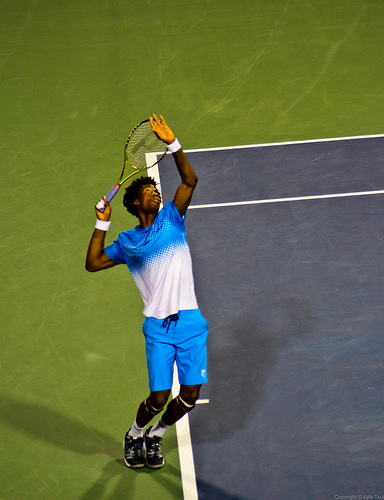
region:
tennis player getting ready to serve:
[75, 103, 220, 477]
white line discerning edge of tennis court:
[169, 385, 208, 498]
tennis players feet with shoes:
[113, 419, 181, 478]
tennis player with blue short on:
[134, 306, 216, 394]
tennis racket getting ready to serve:
[91, 113, 180, 224]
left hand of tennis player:
[144, 104, 182, 145]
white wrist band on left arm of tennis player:
[161, 134, 185, 158]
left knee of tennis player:
[178, 382, 203, 412]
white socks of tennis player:
[125, 417, 175, 441]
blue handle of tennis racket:
[92, 175, 127, 214]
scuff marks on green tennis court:
[36, 290, 57, 335]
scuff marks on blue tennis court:
[289, 220, 322, 241]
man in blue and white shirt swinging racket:
[84, 116, 197, 313]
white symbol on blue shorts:
[199, 368, 206, 379]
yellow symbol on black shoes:
[131, 435, 137, 438]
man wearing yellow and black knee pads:
[141, 398, 164, 419]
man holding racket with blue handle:
[92, 183, 118, 219]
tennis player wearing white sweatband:
[147, 111, 200, 157]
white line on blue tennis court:
[283, 192, 336, 203]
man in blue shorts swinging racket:
[81, 117, 203, 392]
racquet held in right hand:
[101, 118, 155, 212]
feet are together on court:
[120, 431, 179, 477]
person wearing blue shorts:
[137, 321, 218, 379]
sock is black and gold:
[157, 396, 195, 428]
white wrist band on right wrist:
[90, 219, 116, 226]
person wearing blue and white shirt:
[122, 216, 176, 313]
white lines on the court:
[198, 146, 382, 215]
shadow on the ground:
[5, 390, 133, 489]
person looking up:
[122, 175, 186, 244]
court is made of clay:
[221, 313, 378, 495]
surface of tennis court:
[3, 2, 383, 495]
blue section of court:
[143, 135, 380, 497]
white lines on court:
[145, 131, 381, 498]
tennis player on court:
[85, 115, 212, 469]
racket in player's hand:
[95, 118, 170, 216]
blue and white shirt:
[105, 200, 198, 318]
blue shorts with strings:
[143, 309, 209, 392]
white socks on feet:
[129, 419, 172, 437]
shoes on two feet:
[123, 425, 163, 467]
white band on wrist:
[166, 138, 181, 151]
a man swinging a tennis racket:
[92, 101, 230, 467]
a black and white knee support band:
[140, 396, 164, 416]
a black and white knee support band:
[173, 395, 196, 414]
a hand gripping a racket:
[94, 191, 111, 219]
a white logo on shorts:
[199, 366, 212, 379]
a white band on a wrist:
[92, 215, 115, 233]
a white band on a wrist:
[166, 141, 184, 153]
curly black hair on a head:
[123, 184, 136, 198]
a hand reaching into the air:
[149, 115, 198, 206]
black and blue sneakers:
[120, 429, 160, 466]